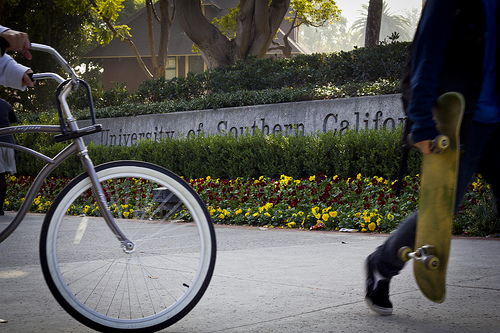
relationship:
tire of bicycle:
[36, 153, 213, 330] [4, 45, 300, 328]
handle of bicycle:
[25, 25, 82, 89] [4, 45, 300, 328]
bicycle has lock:
[4, 45, 300, 328] [47, 74, 124, 151]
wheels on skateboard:
[430, 134, 451, 153] [400, 76, 472, 309]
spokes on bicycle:
[67, 180, 202, 304] [4, 45, 300, 328]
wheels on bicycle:
[430, 134, 451, 153] [4, 45, 300, 328]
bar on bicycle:
[25, 25, 82, 89] [4, 45, 300, 328]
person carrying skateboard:
[313, 4, 496, 317] [400, 76, 472, 309]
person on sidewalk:
[363, 0, 496, 317] [1, 183, 500, 322]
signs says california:
[95, 93, 416, 165] [292, 81, 420, 162]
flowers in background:
[231, 173, 406, 241] [187, 156, 414, 235]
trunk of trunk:
[191, 21, 304, 86] [170, 0, 291, 101]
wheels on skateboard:
[390, 115, 461, 171] [400, 76, 472, 309]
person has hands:
[313, 4, 496, 317] [400, 125, 446, 160]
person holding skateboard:
[313, 4, 496, 317] [400, 76, 472, 309]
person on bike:
[11, 32, 109, 182] [4, 45, 300, 328]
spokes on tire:
[67, 180, 202, 304] [36, 153, 213, 330]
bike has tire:
[4, 45, 300, 328] [36, 153, 213, 330]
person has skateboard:
[313, 4, 496, 317] [400, 76, 472, 309]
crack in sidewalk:
[238, 281, 357, 332] [1, 183, 500, 322]